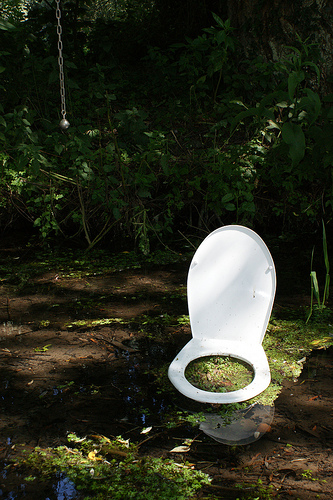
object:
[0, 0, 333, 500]
grass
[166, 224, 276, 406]
toilet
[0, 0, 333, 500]
garden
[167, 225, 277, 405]
lid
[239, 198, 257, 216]
leaf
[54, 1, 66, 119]
chain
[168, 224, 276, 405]
white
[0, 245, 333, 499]
dirt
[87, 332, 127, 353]
twig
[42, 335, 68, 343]
twig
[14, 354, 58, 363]
twig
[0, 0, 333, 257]
tree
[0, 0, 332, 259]
greenery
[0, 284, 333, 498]
water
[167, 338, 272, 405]
toilet seat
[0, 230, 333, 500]
ground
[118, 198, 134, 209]
leaf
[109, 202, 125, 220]
leaf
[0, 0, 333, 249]
bushes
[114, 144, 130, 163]
leaf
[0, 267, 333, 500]
water puddle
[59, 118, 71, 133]
ball